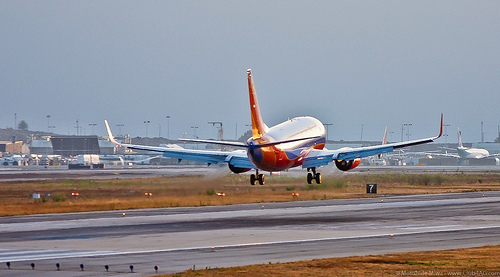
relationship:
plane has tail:
[105, 68, 443, 184] [247, 70, 269, 138]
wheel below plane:
[258, 174, 265, 186] [105, 68, 443, 184]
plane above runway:
[105, 68, 443, 184] [0, 191, 499, 273]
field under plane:
[0, 172, 499, 216] [105, 68, 443, 184]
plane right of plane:
[427, 130, 499, 167] [105, 68, 443, 184]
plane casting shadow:
[105, 68, 443, 184] [2, 215, 396, 239]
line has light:
[2, 261, 162, 270] [152, 263, 159, 274]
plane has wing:
[105, 68, 443, 184] [304, 115, 445, 169]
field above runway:
[0, 172, 499, 216] [0, 191, 499, 273]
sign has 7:
[367, 183, 378, 194] [366, 184, 375, 194]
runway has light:
[0, 191, 499, 273] [152, 263, 159, 274]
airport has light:
[1, 111, 497, 275] [152, 263, 159, 274]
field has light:
[0, 172, 499, 216] [146, 191, 153, 199]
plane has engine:
[105, 68, 443, 184] [333, 160, 360, 171]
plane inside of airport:
[105, 68, 443, 184] [1, 111, 497, 275]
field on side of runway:
[0, 172, 499, 216] [0, 191, 499, 273]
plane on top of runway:
[105, 68, 443, 184] [0, 191, 499, 273]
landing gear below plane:
[304, 167, 323, 184] [105, 68, 443, 184]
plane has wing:
[105, 68, 443, 184] [104, 119, 251, 169]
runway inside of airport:
[0, 191, 499, 273] [1, 111, 497, 275]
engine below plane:
[333, 160, 360, 171] [105, 68, 443, 184]